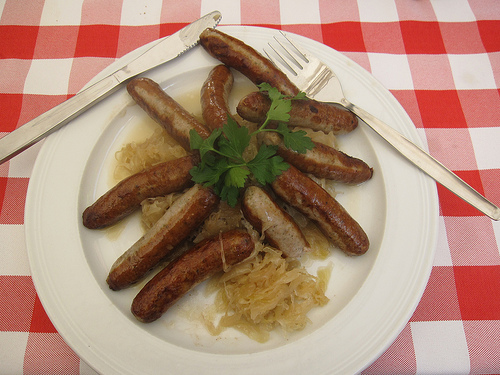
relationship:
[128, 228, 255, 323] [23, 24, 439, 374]
sausage on plate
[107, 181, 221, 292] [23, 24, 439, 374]
sausage on plate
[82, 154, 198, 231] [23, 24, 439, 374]
sausage on plate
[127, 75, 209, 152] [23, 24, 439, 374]
sausage on plate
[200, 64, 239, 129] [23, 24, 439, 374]
sausage on plate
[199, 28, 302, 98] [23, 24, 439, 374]
sausage on plate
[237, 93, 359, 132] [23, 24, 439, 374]
sausage on plate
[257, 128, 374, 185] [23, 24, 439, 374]
sausage on plate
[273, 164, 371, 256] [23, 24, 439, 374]
sausage on plate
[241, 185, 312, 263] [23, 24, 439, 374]
sausage on plate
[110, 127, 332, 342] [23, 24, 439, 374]
sauerkraut on plate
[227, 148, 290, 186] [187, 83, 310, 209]
sprig of parsley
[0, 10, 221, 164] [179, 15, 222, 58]
knife has edge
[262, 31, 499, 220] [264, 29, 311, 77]
fork has tines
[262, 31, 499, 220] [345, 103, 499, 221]
fork has handle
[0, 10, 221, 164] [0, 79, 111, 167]
knife has handle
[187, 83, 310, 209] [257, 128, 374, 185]
parsley on sausage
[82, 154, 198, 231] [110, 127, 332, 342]
sausage on sauerkraut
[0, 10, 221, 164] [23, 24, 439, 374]
knife on plate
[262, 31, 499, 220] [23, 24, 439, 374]
fork on plate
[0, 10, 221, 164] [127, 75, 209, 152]
knife touching sausage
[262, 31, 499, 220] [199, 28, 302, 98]
fork touching sausage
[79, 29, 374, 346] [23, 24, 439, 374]
food on plate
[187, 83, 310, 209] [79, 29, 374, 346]
parsley on food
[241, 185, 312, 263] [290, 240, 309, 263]
sausage has bite